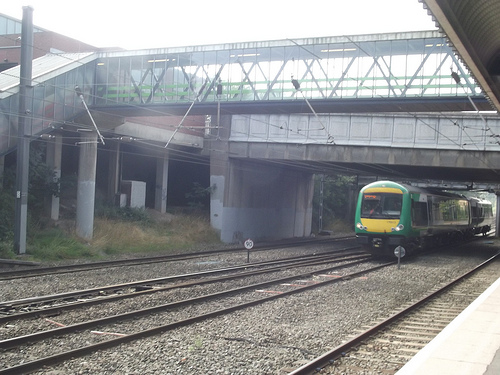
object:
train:
[350, 177, 494, 248]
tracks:
[0, 238, 500, 374]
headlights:
[394, 224, 404, 232]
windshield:
[359, 192, 405, 219]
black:
[244, 240, 254, 250]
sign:
[243, 237, 254, 263]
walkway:
[96, 50, 462, 108]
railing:
[93, 72, 486, 104]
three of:
[1, 235, 293, 373]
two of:
[1, 251, 63, 322]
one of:
[281, 288, 500, 375]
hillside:
[94, 205, 215, 255]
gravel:
[76, 350, 270, 375]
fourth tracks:
[283, 246, 500, 375]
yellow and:
[359, 220, 396, 230]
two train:
[350, 176, 500, 257]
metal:
[12, 3, 35, 258]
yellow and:
[363, 186, 402, 195]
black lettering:
[245, 240, 254, 248]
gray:
[210, 200, 312, 239]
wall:
[210, 163, 316, 241]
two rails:
[1, 321, 401, 375]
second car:
[470, 192, 500, 235]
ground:
[26, 224, 91, 259]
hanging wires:
[348, 77, 498, 174]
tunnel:
[234, 158, 500, 248]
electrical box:
[114, 179, 149, 212]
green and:
[402, 189, 412, 233]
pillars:
[71, 127, 100, 244]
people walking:
[101, 76, 469, 103]